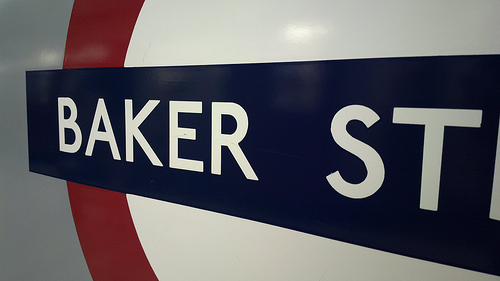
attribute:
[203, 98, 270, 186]
letter — white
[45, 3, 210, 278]
circle — red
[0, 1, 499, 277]
sign — red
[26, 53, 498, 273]
sign — grey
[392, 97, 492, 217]
t — white, letter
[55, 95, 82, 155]
letter — white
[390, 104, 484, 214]
letter — white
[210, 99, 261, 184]
letter — white, R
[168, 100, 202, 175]
letter — white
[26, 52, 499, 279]
stripe — blue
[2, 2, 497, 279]
background — white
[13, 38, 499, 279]
logo — white, blue, red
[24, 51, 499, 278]
street sign — blue and white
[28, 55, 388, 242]
sign — blue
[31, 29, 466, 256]
surface — white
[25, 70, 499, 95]
background — blue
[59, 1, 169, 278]
red line — curverd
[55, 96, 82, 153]
letter b —  white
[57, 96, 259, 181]
lettering — white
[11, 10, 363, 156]
glare — light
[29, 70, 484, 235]
surface — blue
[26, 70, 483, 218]
background — blue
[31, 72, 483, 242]
background — blue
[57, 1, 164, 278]
circle — red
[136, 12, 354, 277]
background — white